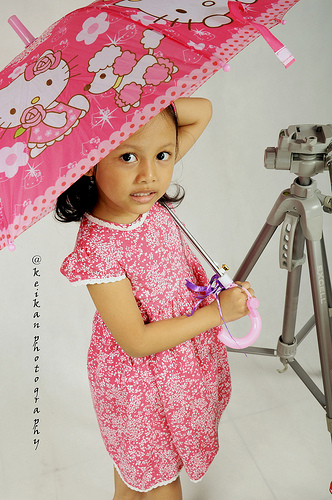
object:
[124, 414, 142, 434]
flower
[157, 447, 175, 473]
flower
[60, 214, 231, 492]
dress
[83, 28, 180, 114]
poodle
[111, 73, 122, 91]
yellow collar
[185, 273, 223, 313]
ribbon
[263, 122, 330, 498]
tripod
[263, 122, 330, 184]
camera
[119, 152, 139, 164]
eyes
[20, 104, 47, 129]
rose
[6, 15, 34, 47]
tip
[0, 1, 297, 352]
umbrella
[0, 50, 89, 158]
hello kitty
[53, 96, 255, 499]
girl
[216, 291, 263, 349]
handle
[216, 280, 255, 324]
hand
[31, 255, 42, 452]
copyright letters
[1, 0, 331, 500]
photo studio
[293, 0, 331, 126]
backdrop